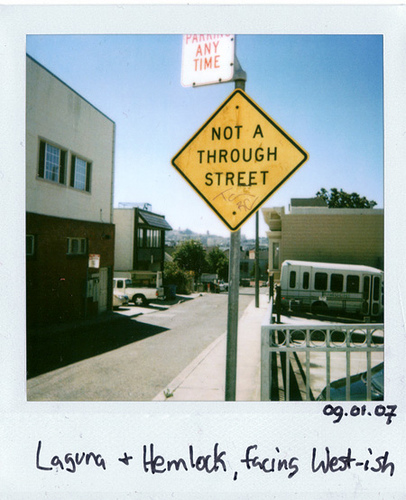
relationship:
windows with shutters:
[46, 144, 65, 181] [35, 132, 46, 185]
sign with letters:
[180, 33, 230, 82] [192, 40, 225, 68]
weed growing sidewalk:
[155, 387, 179, 400] [159, 296, 283, 398]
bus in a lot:
[275, 256, 384, 327] [145, 316, 185, 357]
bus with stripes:
[281, 256, 382, 320] [283, 288, 308, 304]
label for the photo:
[35, 442, 387, 481] [48, 49, 377, 393]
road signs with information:
[165, 87, 314, 233] [202, 123, 275, 188]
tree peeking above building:
[313, 188, 366, 206] [284, 205, 382, 255]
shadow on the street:
[29, 352, 108, 377] [123, 324, 173, 367]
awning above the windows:
[138, 212, 167, 225] [134, 226, 165, 240]